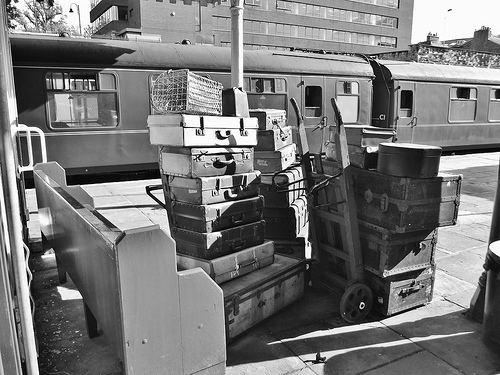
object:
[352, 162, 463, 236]
chests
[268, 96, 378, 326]
train carts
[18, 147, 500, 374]
sidewalk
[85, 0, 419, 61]
building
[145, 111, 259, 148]
luggage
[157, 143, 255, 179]
luggage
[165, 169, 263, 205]
luggage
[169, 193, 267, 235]
luggage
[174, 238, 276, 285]
luggage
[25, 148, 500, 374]
ground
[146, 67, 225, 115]
cage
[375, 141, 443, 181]
box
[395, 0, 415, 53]
wall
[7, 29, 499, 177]
train